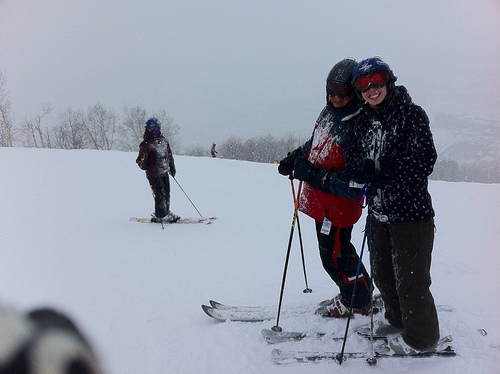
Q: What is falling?
A: Snow.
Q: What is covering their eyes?
A: Goggles.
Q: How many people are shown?
A: 4.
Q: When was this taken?
A: Daytime.